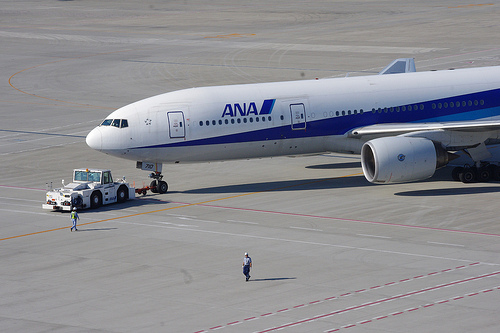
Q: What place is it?
A: It is a runway.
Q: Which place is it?
A: It is a runway.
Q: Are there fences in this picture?
A: No, there are no fences.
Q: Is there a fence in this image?
A: No, there are no fences.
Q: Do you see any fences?
A: No, there are no fences.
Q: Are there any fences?
A: No, there are no fences.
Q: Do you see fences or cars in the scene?
A: No, there are no fences or cars.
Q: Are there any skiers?
A: No, there are no skiers.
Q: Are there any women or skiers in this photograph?
A: No, there are no skiers or women.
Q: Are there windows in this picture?
A: Yes, there is a window.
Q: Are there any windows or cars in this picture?
A: Yes, there is a window.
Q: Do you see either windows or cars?
A: Yes, there is a window.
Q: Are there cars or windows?
A: Yes, there is a window.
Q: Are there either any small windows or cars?
A: Yes, there is a small window.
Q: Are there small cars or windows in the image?
A: Yes, there is a small window.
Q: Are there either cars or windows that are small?
A: Yes, the window is small.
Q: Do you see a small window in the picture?
A: Yes, there is a small window.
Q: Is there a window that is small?
A: Yes, there is a window that is small.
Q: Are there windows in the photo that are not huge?
A: Yes, there is a small window.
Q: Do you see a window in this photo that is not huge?
A: Yes, there is a small window.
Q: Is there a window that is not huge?
A: Yes, there is a small window.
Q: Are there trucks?
A: Yes, there is a truck.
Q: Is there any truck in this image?
A: Yes, there is a truck.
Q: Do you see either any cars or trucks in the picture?
A: Yes, there is a truck.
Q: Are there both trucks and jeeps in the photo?
A: No, there is a truck but no jeeps.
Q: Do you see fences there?
A: No, there are no fences.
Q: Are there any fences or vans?
A: No, there are no fences or vans.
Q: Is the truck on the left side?
A: Yes, the truck is on the left of the image.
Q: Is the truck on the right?
A: No, the truck is on the left of the image.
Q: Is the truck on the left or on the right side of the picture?
A: The truck is on the left of the image.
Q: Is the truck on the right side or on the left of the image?
A: The truck is on the left of the image.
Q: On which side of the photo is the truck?
A: The truck is on the left of the image.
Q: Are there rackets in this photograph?
A: No, there are no rackets.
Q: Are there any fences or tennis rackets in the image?
A: No, there are no tennis rackets or fences.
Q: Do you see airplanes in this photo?
A: Yes, there is an airplane.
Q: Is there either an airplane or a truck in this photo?
A: Yes, there is an airplane.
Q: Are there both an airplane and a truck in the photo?
A: Yes, there are both an airplane and a truck.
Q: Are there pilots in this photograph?
A: No, there are no pilots.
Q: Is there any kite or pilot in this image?
A: No, there are no pilots or kites.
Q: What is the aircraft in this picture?
A: The aircraft is an airplane.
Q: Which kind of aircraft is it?
A: The aircraft is an airplane.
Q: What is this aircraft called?
A: This is an airplane.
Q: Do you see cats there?
A: No, there are no cats.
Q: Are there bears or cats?
A: No, there are no cats or bears.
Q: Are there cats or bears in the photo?
A: No, there are no cats or bears.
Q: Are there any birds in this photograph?
A: No, there are no birds.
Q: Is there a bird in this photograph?
A: No, there are no birds.